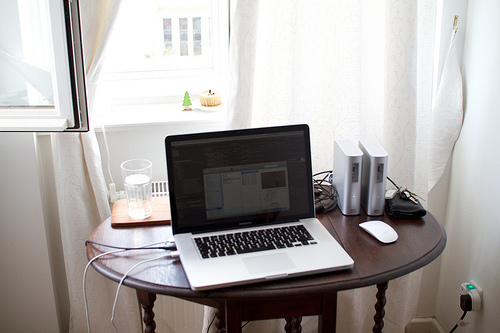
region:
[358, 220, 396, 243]
white flat cordless computer mouse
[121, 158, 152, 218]
clear plastic water glass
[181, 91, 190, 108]
bright green tree in window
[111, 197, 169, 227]
wooden tray on the table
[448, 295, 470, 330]
black cord plugged into the wall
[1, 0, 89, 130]
part of window with white frame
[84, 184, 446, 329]
round dark brown wooden table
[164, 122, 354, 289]
open laptop computer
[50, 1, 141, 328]
white curtain that is tied back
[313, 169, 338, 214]
tangle of black cords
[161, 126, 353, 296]
an Apple MacBook computer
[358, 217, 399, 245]
a white Apple Magic Mouse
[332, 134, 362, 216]
an external hard drive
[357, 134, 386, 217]
an external hard drive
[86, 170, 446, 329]
a round wood table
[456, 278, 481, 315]
a white surge protector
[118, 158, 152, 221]
a clear glass of water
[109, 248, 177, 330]
a white USB cord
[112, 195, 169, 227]
a brown wood tray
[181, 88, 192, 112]
a small green Christmas tree decoration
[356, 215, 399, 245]
a white computer mouse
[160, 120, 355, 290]
a gray laptop computer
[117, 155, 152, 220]
a tall clear glass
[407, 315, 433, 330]
part of a white wall trim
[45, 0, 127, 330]
part of a white curtain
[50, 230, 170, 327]
a long white cord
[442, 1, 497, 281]
part of a white wall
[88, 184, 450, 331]
part of a brown table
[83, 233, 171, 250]
part of a black cord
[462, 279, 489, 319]
a white wall outlet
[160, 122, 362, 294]
LAPTOP READY TO BE USED.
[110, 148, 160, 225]
A clear glass of water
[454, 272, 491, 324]
An electronic outlet with a green "on" light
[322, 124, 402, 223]
two external data storage drives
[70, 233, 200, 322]
several usb cords plugged into laptop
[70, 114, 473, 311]
laptop work station facing an open window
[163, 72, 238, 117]
colorful window sill decorations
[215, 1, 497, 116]
white sheer flowing curtains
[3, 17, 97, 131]
an open window frame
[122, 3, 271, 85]
view of a neighbor's window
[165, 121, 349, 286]
a grey and black open laptop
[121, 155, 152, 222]
a tall clear glass filled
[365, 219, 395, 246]
a sleek white wireless mouse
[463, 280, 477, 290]
a blue light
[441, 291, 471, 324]
a black large plug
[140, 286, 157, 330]
the twisted wooden leg of the table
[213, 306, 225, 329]
the twisted wooden leg of the table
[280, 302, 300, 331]
the twisted wooden leg of the table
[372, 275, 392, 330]
the twisted wooden leg of the table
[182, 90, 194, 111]
a small decorative christmas tree